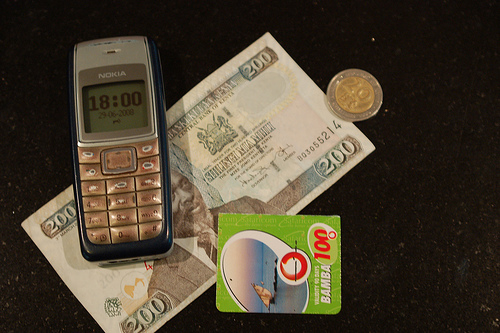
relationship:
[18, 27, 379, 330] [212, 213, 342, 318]
money under card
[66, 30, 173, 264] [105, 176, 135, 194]
cell phone has button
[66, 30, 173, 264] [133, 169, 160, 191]
cell phone has button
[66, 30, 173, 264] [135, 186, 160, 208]
cell phone has button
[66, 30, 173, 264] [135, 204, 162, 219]
cell phone has button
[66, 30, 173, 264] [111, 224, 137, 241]
cell phone has button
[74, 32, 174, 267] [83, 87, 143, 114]
phone showing time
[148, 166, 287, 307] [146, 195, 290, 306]
man in suit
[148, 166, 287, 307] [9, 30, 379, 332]
man on bill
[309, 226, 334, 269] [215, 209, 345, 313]
100 on card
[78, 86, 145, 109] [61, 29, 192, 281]
time on phone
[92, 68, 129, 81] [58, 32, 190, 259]
name on phone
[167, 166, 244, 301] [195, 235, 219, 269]
man wearing tie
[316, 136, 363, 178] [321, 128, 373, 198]
numbers in corner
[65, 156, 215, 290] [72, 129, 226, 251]
numbers faded from buttons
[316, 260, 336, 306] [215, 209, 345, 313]
words on card